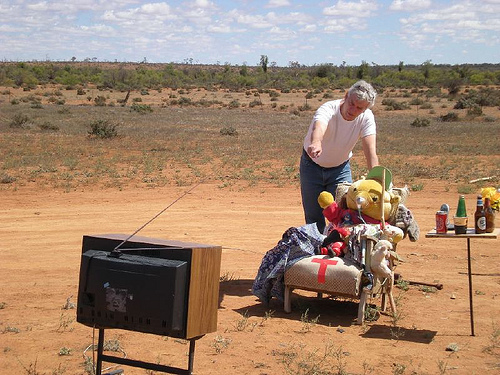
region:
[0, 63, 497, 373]
A desert landscape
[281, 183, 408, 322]
a small cushioned chair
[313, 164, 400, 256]
A large golden colored teddy bear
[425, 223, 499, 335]
A small wooden table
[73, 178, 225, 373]
A television on the ground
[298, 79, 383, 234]
A man in a white shirt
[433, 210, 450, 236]
an aluminum can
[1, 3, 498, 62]
A clear blue sky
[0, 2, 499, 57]
some clouds in the sky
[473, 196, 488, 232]
A brown glass bottle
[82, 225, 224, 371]
television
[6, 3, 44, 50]
white clouds in blue sky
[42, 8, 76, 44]
white clouds in blue sky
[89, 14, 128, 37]
white clouds in blue sky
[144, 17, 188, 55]
white clouds in blue sky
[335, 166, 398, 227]
winnie the poo bear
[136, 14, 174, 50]
white clouds in blue sky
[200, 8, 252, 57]
white clouds in blue sky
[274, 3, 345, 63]
white clouds in blue sky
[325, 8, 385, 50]
white clouds in blue sky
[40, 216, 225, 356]
brown and black tv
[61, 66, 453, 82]
bushels in desert distance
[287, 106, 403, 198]
man pointing at TV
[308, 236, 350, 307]
red cross on bench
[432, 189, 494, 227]
multiple condiments on table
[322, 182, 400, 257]
yellow bear on chair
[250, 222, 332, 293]
blue shirt on chair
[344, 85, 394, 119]
man with gray hair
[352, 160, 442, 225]
green hat on man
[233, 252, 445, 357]
shadow of all the items on the chair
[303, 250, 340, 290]
red cross on the chair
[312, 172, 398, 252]
teddy bear with red shirt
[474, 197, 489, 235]
bottle of tabasco sauce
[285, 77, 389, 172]
guy pointing to the tv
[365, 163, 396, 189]
green cap on the teddy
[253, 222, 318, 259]
blue cloth on the chair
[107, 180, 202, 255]
rabbit ears on the tv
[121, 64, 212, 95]
green bushes on the ground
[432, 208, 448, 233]
coke can on the stand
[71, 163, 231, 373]
wood sided television in desert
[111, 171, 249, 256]
long metal antenna on television in desert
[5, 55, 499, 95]
green foliage in desert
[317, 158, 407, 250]
yellow stuffed animal in chair in desert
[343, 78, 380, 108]
grey hair on man's head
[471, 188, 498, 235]
two bottles of condiments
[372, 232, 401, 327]
white stuffed animal on side of chair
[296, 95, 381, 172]
white cotton short sleeve t-shirt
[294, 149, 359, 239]
pair of blue jeans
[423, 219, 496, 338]
wooden table on thin pole stuck in desert dirt